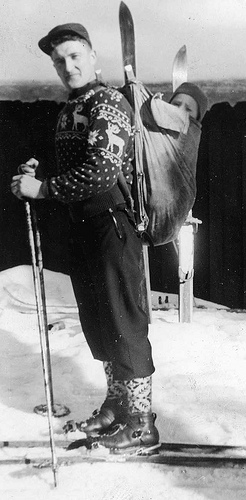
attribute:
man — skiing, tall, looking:
[11, 17, 159, 456]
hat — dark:
[34, 21, 90, 50]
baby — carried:
[167, 79, 207, 122]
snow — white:
[1, 259, 244, 497]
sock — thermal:
[125, 377, 154, 411]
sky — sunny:
[2, 1, 242, 79]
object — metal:
[176, 208, 193, 322]